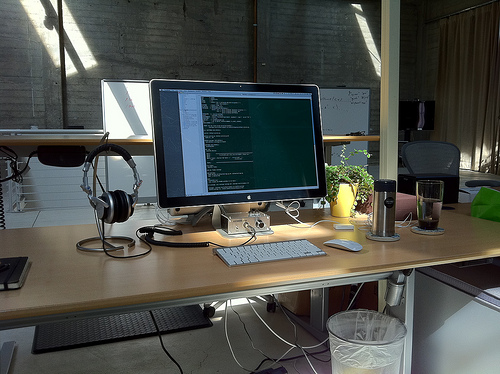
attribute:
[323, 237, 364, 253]
mouse — white, wireless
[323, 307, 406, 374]
basket — empty, plastic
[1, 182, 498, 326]
desk — wooden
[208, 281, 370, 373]
cords — hanging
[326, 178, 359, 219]
pot — yellow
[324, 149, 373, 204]
plant — green, small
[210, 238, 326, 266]
keyboard — white, wireless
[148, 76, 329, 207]
monitor — on, apple, flat, black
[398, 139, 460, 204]
chair — black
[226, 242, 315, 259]
keys — white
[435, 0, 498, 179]
curtain — long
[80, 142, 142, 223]
headphones — silver, black, hanging, silvery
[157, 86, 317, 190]
screen — flat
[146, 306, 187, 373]
cable — black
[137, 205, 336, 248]
wires — bunched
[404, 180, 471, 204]
seat — black